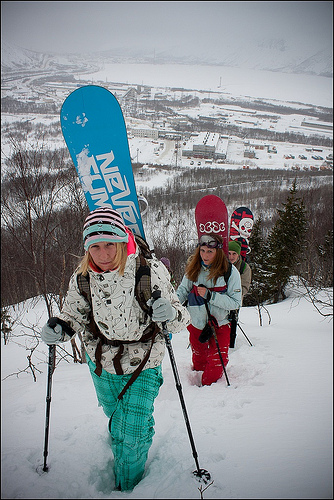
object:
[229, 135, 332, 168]
parking lot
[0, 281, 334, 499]
hill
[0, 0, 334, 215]
ground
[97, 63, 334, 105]
snow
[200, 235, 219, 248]
goggles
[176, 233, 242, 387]
girl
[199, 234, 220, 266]
head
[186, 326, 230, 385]
red snowpants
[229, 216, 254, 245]
skull design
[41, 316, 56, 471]
pole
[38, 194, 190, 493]
girl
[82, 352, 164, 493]
green snowpants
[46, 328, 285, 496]
snow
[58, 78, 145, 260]
snowboard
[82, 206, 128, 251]
cap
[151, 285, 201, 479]
ski pole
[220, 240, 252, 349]
person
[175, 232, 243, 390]
person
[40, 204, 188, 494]
person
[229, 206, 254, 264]
snowboard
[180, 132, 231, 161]
building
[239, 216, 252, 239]
skull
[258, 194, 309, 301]
pine tree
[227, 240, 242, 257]
green hat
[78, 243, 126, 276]
blonde hair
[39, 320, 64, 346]
hand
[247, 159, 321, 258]
distance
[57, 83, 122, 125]
top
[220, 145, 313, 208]
bottom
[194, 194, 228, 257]
snowboard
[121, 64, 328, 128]
distance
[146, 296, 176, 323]
hand